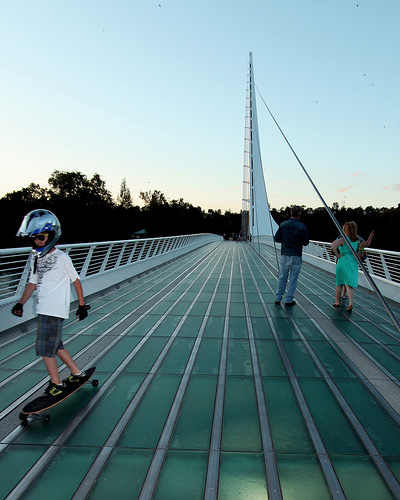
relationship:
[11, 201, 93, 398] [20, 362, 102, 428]
boy on skateboard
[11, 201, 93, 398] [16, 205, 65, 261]
boy wearing helmet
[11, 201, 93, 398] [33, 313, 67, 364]
boy wearing shorts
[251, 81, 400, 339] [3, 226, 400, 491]
suspension on bridge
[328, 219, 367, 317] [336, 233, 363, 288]
woman wearing dress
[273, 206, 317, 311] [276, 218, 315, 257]
man wearing shirt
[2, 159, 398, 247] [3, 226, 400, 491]
trees next to bridge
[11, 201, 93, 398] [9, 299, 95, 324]
boy wearing gloves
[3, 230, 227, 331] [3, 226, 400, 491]
railing along bridge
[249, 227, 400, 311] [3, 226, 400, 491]
railing along bridge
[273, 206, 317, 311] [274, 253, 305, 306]
man wearing jeans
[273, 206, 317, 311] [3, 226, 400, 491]
person on bridge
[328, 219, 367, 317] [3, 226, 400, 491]
person on bridge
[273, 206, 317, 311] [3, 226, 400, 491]
person walking on bridge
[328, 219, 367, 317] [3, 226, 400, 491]
person walking on bridge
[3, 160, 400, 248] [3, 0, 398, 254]
landscape in background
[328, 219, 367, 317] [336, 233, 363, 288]
woman in dress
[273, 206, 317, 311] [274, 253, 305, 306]
man in jeans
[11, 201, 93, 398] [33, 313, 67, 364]
boy in shorts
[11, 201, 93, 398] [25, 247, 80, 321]
boy in t-shirt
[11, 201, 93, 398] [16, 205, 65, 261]
kid in helmet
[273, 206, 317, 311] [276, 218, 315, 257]
man in shirt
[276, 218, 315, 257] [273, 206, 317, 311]
shirt worn by man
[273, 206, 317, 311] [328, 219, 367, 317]
man walking with woman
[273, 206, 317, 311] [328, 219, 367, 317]
man with woman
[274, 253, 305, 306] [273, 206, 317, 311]
jeans worn by man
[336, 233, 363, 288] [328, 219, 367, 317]
dress worn by woman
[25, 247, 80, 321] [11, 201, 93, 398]
t-shirt worn by boy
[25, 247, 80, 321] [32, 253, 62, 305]
t-shirt with design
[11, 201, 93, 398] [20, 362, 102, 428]
boy riding skateboard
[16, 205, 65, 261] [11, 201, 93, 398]
helmet worn by boy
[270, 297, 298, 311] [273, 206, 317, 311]
shoes worn by man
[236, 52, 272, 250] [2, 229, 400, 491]
structure attached to pathway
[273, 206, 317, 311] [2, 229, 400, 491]
person walking on pathway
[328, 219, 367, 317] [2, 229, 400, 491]
person walking on pathway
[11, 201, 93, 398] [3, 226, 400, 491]
person on bridge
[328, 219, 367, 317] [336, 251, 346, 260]
woman has hand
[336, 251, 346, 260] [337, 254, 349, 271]
hand on hip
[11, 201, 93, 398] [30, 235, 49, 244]
boy wearing suglasses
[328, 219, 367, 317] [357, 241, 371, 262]
woman has purse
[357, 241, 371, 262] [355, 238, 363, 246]
purse on shoulder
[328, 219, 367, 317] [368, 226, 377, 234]
woman pointing with hand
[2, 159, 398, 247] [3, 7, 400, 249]
trees in distance